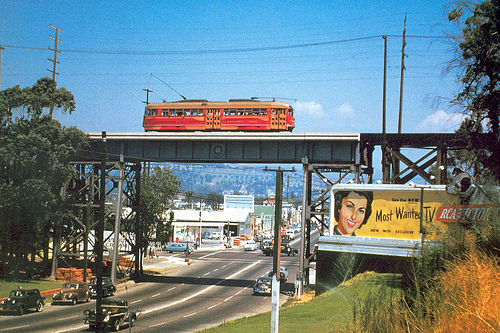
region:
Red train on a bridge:
[127, 93, 305, 146]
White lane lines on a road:
[215, 290, 235, 310]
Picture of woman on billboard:
[330, 184, 374, 240]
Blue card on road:
[160, 237, 194, 258]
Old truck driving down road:
[77, 290, 143, 330]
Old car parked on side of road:
[0, 283, 51, 318]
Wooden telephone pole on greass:
[260, 163, 301, 331]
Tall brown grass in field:
[403, 256, 476, 331]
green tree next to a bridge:
[8, 126, 60, 249]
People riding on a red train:
[224, 105, 274, 121]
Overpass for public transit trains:
[65, 92, 498, 307]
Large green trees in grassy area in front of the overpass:
[0, 65, 90, 275]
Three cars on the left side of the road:
[0, 270, 116, 315]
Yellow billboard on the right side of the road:
[310, 166, 495, 259]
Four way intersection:
[175, 235, 315, 265]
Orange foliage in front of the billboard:
[400, 240, 495, 330]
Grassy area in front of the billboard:
[190, 265, 405, 330]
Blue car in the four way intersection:
[158, 235, 197, 257]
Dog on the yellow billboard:
[440, 165, 495, 231]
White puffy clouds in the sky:
[289, 90, 493, 137]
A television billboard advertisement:
[332, 185, 460, 243]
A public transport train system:
[136, 95, 297, 130]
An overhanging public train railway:
[42, 120, 492, 265]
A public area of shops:
[156, 190, 321, 255]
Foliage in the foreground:
[345, 225, 495, 330]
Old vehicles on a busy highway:
[0, 272, 138, 327]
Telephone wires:
[1, 21, 493, 96]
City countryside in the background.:
[135, 157, 314, 195]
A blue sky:
[3, 0, 499, 135]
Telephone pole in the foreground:
[261, 162, 293, 329]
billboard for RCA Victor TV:
[328, 168, 496, 240]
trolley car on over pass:
[142, 93, 297, 130]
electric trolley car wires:
[77, 35, 379, 85]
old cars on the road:
[3, 272, 150, 330]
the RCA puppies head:
[443, 165, 483, 202]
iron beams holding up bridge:
[73, 147, 355, 290]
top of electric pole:
[45, 20, 66, 76]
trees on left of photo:
[2, 75, 88, 278]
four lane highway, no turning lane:
[128, 280, 258, 316]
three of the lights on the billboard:
[333, 178, 435, 188]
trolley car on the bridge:
[139, 90, 300, 136]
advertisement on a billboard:
[321, 181, 453, 244]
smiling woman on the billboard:
[334, 188, 372, 240]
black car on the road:
[2, 284, 44, 316]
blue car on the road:
[165, 238, 191, 255]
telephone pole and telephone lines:
[43, 35, 435, 87]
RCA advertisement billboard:
[434, 165, 495, 227]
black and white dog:
[438, 165, 495, 206]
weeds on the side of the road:
[355, 225, 498, 330]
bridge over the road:
[82, 116, 440, 172]